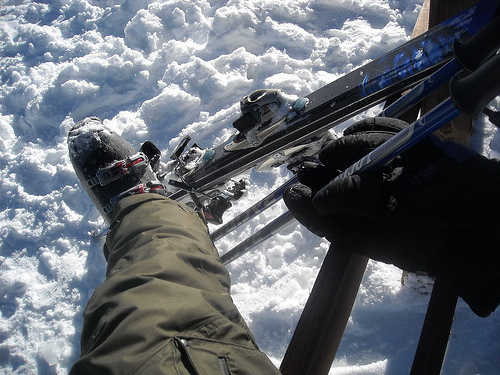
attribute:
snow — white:
[16, 9, 335, 71]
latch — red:
[93, 148, 147, 183]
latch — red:
[108, 175, 170, 208]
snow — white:
[1, 2, 408, 118]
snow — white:
[2, 129, 84, 371]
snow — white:
[237, 42, 282, 73]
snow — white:
[194, 26, 276, 86]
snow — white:
[57, 79, 102, 101]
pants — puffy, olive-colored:
[68, 192, 283, 374]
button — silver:
[177, 336, 189, 349]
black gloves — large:
[281, 116, 498, 319]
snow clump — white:
[51, 55, 136, 101]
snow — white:
[0, 0, 499, 374]